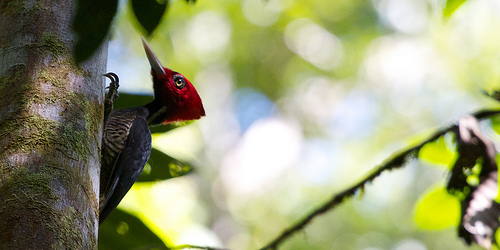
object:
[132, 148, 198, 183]
leaf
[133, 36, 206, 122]
head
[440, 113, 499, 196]
flowers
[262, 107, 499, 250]
branch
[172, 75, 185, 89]
eye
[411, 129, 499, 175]
leaves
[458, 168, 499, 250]
flowers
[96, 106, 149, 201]
feathers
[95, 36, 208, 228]
woodpecker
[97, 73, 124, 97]
claws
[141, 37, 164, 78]
beak